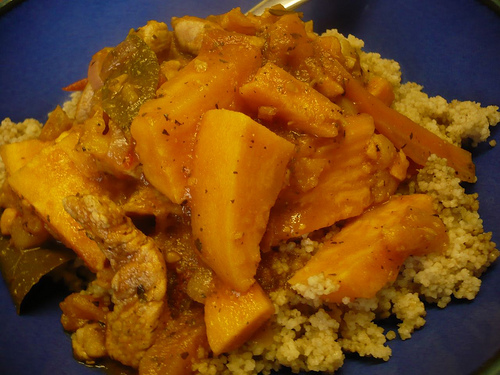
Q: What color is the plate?
A: Blue.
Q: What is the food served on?
A: Plate.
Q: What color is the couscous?
A: Tan.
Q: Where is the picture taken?
A: In a restaurant.